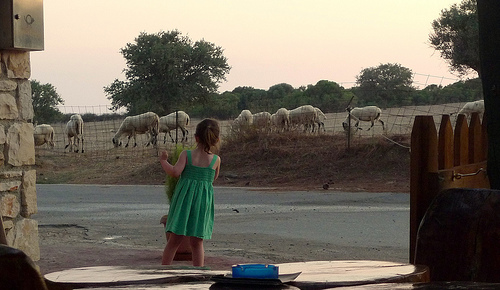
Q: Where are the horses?
A: Out in pasture.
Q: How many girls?
A: One.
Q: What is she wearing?
A: A dress.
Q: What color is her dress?
A: Green.